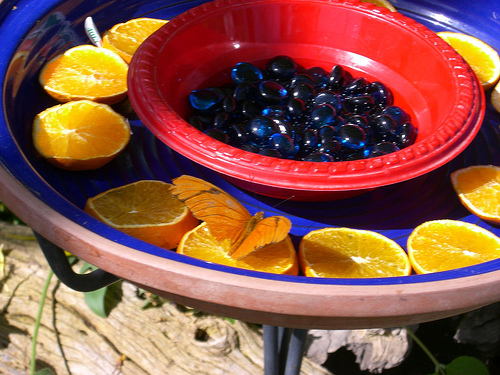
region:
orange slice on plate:
[100, 8, 166, 66]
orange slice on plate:
[30, 30, 133, 107]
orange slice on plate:
[86, 171, 192, 255]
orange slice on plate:
[173, 206, 298, 285]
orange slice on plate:
[298, 215, 413, 287]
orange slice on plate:
[403, 210, 498, 268]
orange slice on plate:
[438, 154, 499, 224]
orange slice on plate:
[431, 20, 496, 92]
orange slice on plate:
[488, 80, 499, 107]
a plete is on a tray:
[50, 22, 493, 183]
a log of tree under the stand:
[40, 275, 178, 371]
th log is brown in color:
[21, 284, 160, 373]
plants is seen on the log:
[17, 259, 118, 374]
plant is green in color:
[40, 256, 141, 366]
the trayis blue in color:
[103, 170, 285, 332]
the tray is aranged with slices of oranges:
[124, 178, 311, 308]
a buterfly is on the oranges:
[180, 188, 282, 275]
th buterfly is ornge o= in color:
[203, 185, 295, 267]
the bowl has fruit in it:
[115, 15, 489, 372]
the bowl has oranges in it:
[114, 192, 275, 347]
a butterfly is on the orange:
[183, 183, 405, 372]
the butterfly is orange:
[171, 163, 391, 374]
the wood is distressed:
[57, 320, 115, 337]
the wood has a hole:
[185, 309, 284, 367]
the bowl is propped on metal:
[235, 279, 275, 359]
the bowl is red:
[121, 33, 413, 288]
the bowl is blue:
[2, 40, 249, 254]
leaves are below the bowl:
[400, 325, 451, 372]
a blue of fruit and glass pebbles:
[8, 3, 497, 326]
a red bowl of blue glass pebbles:
[126, 0, 482, 192]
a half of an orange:
[296, 218, 409, 281]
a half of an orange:
[408, 215, 499, 278]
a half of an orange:
[452, 169, 499, 210]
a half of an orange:
[106, 18, 162, 58]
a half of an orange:
[43, 53, 133, 95]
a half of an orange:
[25, 108, 131, 160]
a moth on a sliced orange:
[166, 170, 294, 287]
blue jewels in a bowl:
[176, 35, 407, 150]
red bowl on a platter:
[125, 30, 452, 186]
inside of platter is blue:
[13, 24, 473, 311]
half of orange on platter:
[33, 94, 128, 171]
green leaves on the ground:
[22, 252, 118, 327]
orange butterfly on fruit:
[169, 166, 289, 260]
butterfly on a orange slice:
[175, 173, 295, 278]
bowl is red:
[123, 12, 470, 195]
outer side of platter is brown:
[3, 15, 486, 345]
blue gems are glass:
[196, 54, 413, 153]